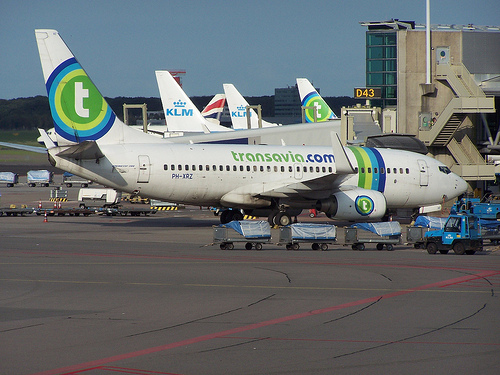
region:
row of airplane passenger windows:
[159, 162, 411, 175]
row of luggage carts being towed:
[195, 214, 446, 253]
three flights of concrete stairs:
[415, 61, 497, 183]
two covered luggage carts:
[0, 167, 53, 189]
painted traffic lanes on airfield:
[1, 246, 498, 372]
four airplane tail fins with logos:
[33, 27, 340, 147]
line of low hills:
[0, 93, 272, 137]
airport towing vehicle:
[422, 213, 484, 258]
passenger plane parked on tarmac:
[32, 26, 473, 227]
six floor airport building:
[358, 17, 498, 144]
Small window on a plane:
[157, 158, 172, 179]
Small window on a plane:
[168, 158, 179, 170]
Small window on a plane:
[178, 163, 185, 180]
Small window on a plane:
[182, 161, 198, 177]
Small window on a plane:
[199, 156, 218, 174]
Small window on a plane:
[220, 161, 238, 178]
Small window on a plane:
[234, 161, 272, 178]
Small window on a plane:
[261, 164, 295, 177]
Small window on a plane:
[285, 159, 329, 174]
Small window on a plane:
[355, 159, 380, 184]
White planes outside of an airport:
[0, 15, 498, 373]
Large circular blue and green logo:
[44, 53, 116, 144]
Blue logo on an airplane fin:
[162, 96, 194, 119]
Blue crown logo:
[170, 96, 187, 107]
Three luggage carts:
[212, 215, 400, 250]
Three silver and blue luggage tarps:
[219, 219, 403, 242]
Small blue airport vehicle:
[425, 213, 483, 257]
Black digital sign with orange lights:
[353, 86, 382, 98]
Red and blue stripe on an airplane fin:
[198, 93, 226, 120]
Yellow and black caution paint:
[47, 193, 67, 203]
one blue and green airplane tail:
[31, 17, 120, 147]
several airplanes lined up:
[30, 22, 485, 224]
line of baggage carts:
[198, 204, 485, 256]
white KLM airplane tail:
[149, 64, 219, 134]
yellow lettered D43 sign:
[352, 82, 382, 101]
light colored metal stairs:
[413, 38, 498, 145]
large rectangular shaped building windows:
[361, 27, 403, 84]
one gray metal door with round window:
[431, 41, 457, 68]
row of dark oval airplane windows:
[160, 159, 338, 176]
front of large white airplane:
[422, 151, 473, 206]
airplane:
[84, 133, 456, 231]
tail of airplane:
[28, 33, 111, 144]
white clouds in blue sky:
[73, 4, 110, 44]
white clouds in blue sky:
[93, 34, 130, 74]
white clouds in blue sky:
[187, 10, 220, 49]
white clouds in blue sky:
[305, 21, 338, 48]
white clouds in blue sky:
[199, 25, 294, 60]